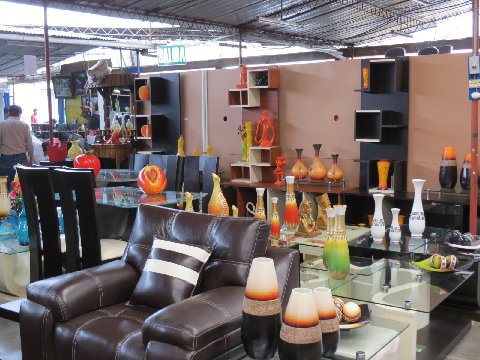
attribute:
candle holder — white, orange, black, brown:
[234, 248, 286, 358]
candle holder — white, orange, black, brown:
[283, 278, 326, 358]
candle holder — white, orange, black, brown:
[312, 283, 340, 357]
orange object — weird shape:
[252, 107, 278, 152]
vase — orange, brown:
[325, 151, 346, 183]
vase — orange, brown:
[307, 142, 326, 181]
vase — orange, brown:
[289, 148, 305, 177]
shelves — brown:
[344, 59, 414, 163]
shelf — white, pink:
[206, 51, 297, 197]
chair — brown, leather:
[30, 181, 340, 357]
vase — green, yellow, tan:
[321, 198, 351, 280]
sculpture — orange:
[134, 163, 166, 195]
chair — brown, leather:
[18, 212, 301, 358]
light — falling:
[4, 3, 173, 36]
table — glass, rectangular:
[110, 187, 478, 348]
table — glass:
[93, 175, 207, 227]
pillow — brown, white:
[125, 231, 234, 325]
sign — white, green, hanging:
[156, 43, 190, 64]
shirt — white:
[0, 126, 37, 160]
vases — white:
[375, 166, 437, 244]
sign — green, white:
[146, 42, 196, 71]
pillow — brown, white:
[122, 232, 219, 315]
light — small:
[237, 251, 280, 332]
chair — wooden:
[19, 173, 125, 262]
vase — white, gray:
[408, 176, 427, 237]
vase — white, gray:
[387, 205, 400, 243]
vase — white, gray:
[370, 190, 385, 243]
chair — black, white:
[53, 164, 101, 273]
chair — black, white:
[13, 164, 63, 280]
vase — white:
[406, 178, 429, 237]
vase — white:
[389, 207, 401, 244]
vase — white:
[370, 191, 387, 241]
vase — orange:
[136, 163, 165, 194]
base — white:
[375, 279, 454, 332]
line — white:
[140, 254, 203, 283]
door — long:
[359, 61, 410, 194]